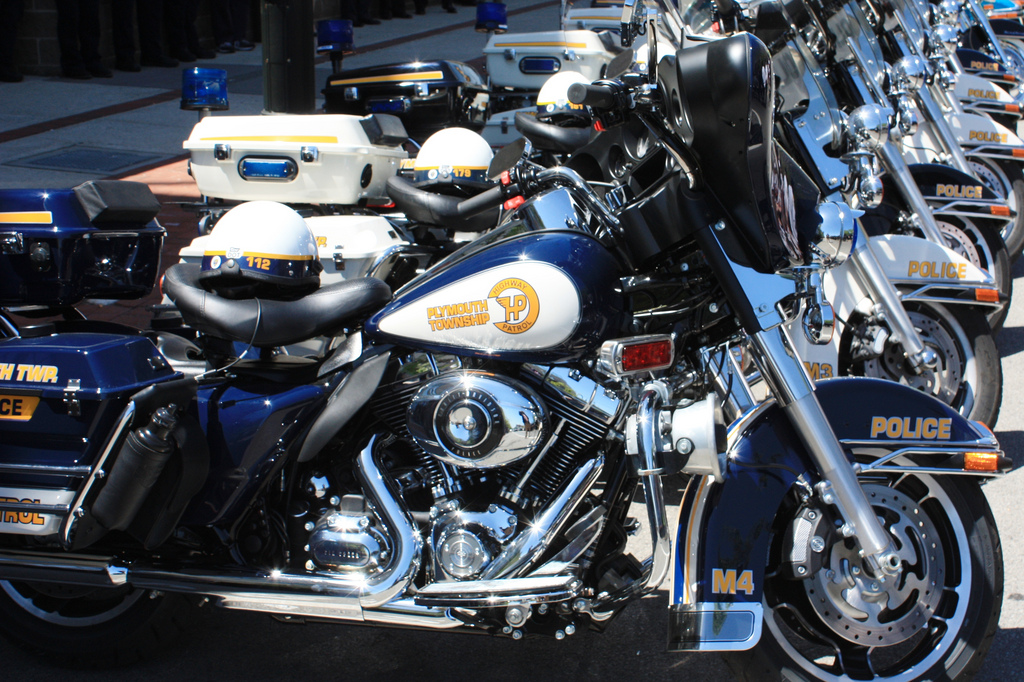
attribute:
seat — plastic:
[160, 257, 372, 352]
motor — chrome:
[373, 392, 627, 631]